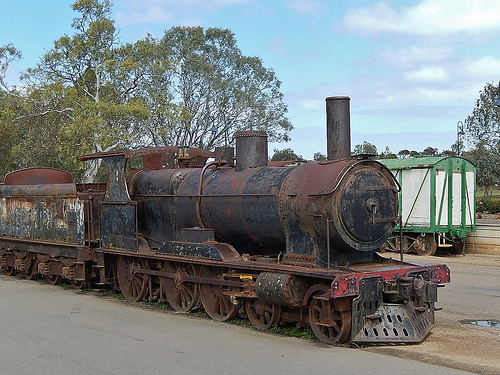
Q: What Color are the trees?
A: Green.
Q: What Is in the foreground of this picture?
A: A train.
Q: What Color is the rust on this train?
A: Brown.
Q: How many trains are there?
A: 2.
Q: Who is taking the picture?
A: Photographer.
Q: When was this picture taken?
A: During the day.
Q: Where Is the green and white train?
A: Background.